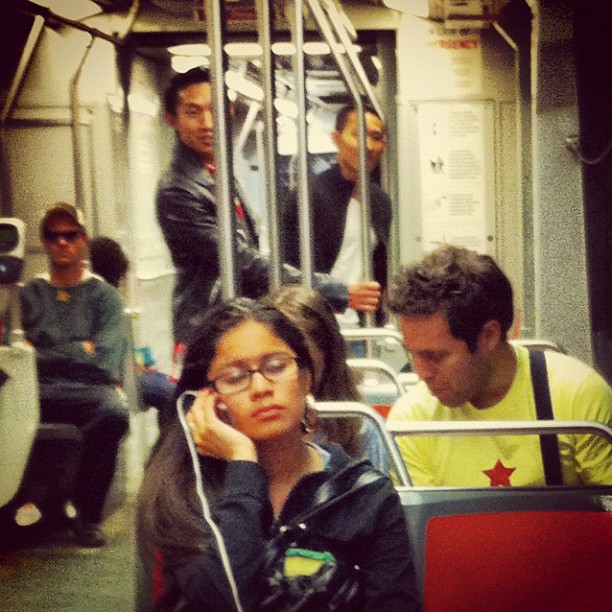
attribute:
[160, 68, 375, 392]
man — asian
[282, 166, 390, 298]
coat — long-sleeved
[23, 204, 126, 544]
man — sitting